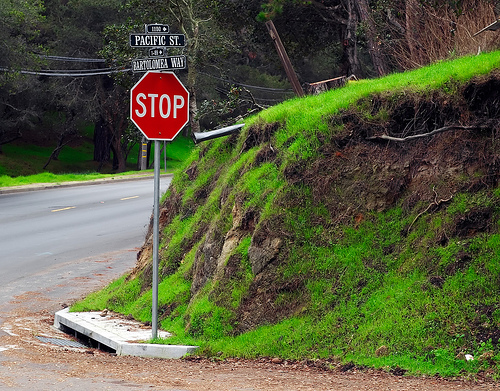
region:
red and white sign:
[123, 73, 195, 141]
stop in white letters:
[128, 87, 187, 124]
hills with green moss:
[99, 45, 498, 376]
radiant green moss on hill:
[245, 36, 498, 181]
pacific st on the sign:
[124, 27, 182, 51]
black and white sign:
[128, 34, 187, 49]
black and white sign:
[121, 53, 184, 70]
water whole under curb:
[58, 321, 101, 353]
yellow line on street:
[42, 197, 80, 223]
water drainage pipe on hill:
[189, 114, 241, 142]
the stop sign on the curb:
[132, 71, 188, 140]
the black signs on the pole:
[123, 20, 189, 69]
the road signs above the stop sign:
[125, 20, 189, 70]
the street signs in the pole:
[124, 23, 189, 339]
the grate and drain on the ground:
[35, 322, 104, 357]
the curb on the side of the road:
[55, 305, 195, 355]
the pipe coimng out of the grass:
[190, 123, 241, 155]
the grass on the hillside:
[160, 146, 286, 326]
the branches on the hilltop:
[378, 3, 498, 70]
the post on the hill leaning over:
[261, 9, 303, 99]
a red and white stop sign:
[122, 70, 194, 143]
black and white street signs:
[118, 21, 186, 72]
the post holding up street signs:
[146, 138, 169, 337]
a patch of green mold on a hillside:
[240, 165, 271, 198]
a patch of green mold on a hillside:
[223, 234, 258, 272]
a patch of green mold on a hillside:
[279, 91, 335, 158]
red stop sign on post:
[132, 65, 196, 152]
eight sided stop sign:
[129, 68, 194, 145]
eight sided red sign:
[124, 60, 197, 148]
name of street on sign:
[132, 55, 189, 70]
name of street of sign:
[134, 32, 184, 49]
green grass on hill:
[100, 280, 160, 319]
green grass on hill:
[276, 108, 328, 163]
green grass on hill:
[224, 157, 292, 206]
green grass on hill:
[342, 283, 437, 323]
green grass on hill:
[177, 275, 233, 354]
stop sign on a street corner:
[125, 20, 196, 311]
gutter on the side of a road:
[33, 288, 185, 383]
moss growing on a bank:
[306, 194, 487, 351]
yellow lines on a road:
[15, 192, 145, 213]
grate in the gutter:
[32, 320, 85, 357]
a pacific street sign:
[130, 32, 186, 47]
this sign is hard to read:
[129, 57, 190, 72]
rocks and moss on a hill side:
[169, 179, 292, 299]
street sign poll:
[150, 145, 163, 337]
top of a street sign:
[128, 71, 193, 139]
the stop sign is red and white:
[129, 69, 188, 143]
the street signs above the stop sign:
[129, 23, 191, 144]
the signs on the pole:
[128, 20, 189, 342]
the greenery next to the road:
[3, 1, 498, 388]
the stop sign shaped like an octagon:
[128, 68, 189, 141]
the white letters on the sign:
[130, 70, 189, 140]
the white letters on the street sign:
[130, 33, 184, 49]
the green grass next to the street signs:
[68, 23, 497, 380]